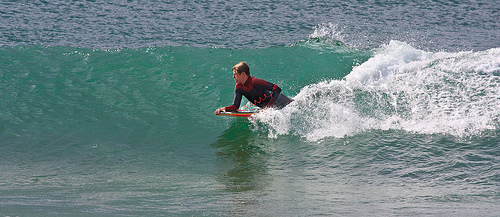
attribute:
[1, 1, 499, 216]
water — blue, settled, calm, green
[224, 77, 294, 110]
suit — red, gray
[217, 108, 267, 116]
surfboard — red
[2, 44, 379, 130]
wave — blue, choppy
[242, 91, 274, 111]
cable — red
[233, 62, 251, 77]
hair — wet